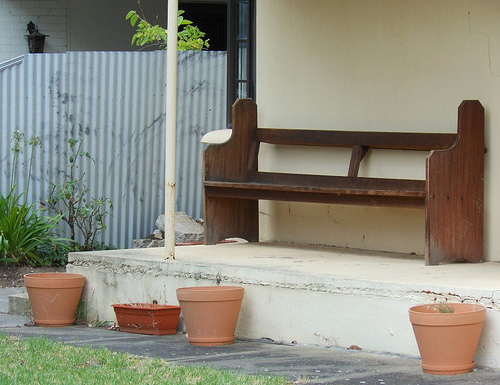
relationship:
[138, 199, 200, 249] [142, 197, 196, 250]
gray racks stack of racks gray racks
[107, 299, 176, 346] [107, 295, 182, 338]
orange planter orange box orange planter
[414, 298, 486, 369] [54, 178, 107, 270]
terra cotta planter with plant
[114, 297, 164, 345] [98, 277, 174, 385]
rectangular terra cotta pot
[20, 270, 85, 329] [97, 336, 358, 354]
terra cotta pot on sidewalk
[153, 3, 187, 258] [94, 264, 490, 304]
white pole holding up porch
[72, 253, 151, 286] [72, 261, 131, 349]
edge of dirty stoop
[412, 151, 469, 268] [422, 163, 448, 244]
wooden end of a bench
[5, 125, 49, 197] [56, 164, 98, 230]
skinny sapling in a garden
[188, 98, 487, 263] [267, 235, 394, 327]
wooden bench on concrete pad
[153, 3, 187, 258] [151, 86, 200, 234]
white pole a support pole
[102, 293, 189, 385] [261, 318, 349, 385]
teracotta plant pot on sidewalk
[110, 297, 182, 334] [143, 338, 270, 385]
rectangular plant pot on ground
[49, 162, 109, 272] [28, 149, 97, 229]
plant with long green leaves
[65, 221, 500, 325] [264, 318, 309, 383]
cement pad against wall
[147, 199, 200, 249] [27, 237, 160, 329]
large rock jagged rock on ground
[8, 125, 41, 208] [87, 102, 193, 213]
thin trees near metal wall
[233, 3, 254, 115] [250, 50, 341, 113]
glass window on wall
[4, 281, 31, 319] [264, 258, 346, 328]
white stone slab step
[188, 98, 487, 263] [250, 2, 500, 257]
wooden bench against beige wall